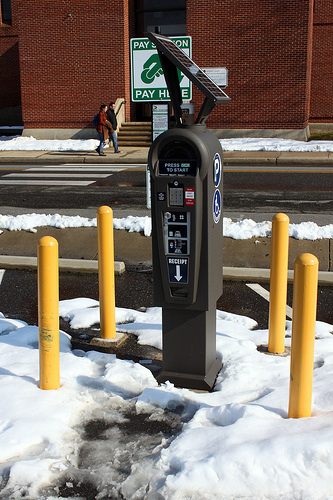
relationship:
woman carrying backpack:
[91, 101, 114, 158] [89, 114, 99, 128]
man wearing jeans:
[106, 101, 121, 154] [108, 132, 122, 155]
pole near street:
[35, 234, 64, 394] [2, 165, 329, 208]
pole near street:
[95, 203, 118, 343] [2, 165, 329, 208]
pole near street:
[266, 212, 289, 358] [2, 165, 329, 208]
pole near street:
[284, 251, 322, 423] [2, 165, 329, 208]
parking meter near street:
[145, 26, 231, 393] [2, 165, 329, 208]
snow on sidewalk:
[5, 208, 149, 239] [2, 208, 331, 280]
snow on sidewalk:
[221, 214, 332, 240] [2, 208, 331, 280]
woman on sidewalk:
[91, 101, 114, 158] [4, 149, 333, 163]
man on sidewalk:
[106, 101, 121, 154] [4, 149, 333, 163]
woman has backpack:
[91, 101, 114, 158] [89, 114, 99, 128]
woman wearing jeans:
[91, 101, 114, 158] [97, 136, 107, 152]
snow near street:
[5, 208, 149, 239] [2, 165, 329, 208]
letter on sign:
[135, 88, 143, 99] [126, 33, 192, 101]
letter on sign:
[141, 88, 148, 102] [126, 33, 192, 101]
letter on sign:
[148, 87, 157, 102] [126, 33, 192, 101]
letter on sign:
[158, 88, 167, 99] [126, 33, 192, 101]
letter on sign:
[134, 41, 139, 50] [126, 33, 192, 101]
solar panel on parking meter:
[149, 29, 233, 103] [145, 26, 231, 393]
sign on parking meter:
[210, 154, 224, 187] [145, 26, 231, 393]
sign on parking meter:
[210, 189, 224, 225] [145, 26, 231, 393]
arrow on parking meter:
[174, 263, 184, 283] [145, 26, 231, 393]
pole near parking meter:
[35, 234, 64, 394] [145, 26, 231, 393]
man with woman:
[106, 101, 121, 154] [91, 101, 114, 158]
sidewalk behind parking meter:
[2, 208, 331, 280] [145, 26, 231, 393]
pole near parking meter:
[95, 203, 118, 343] [145, 26, 231, 393]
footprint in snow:
[3, 442, 47, 492] [2, 323, 133, 500]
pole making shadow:
[284, 251, 322, 423] [75, 372, 259, 422]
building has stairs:
[13, 2, 332, 144] [115, 117, 155, 145]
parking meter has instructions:
[145, 26, 231, 393] [156, 159, 198, 285]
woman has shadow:
[91, 101, 114, 158] [47, 152, 99, 157]